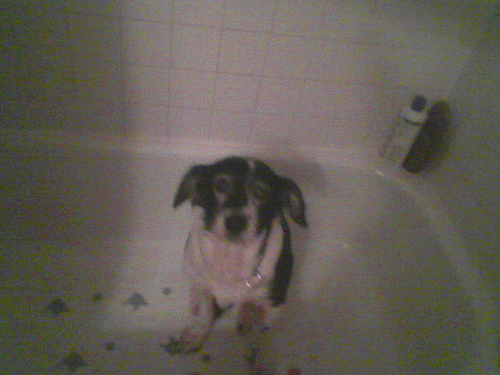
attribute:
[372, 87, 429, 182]
bottles — shampoo, soap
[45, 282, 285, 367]
pattern — GRIPPY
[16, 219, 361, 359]
floor — TUB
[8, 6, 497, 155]
wall — tiled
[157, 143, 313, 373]
dog — black, white,  get a bath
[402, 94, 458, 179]
bottle — black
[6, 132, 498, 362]
tub — white, bath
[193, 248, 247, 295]
fur — white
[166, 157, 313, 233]
ears — down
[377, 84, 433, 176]
bottle — blue, white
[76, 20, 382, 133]
tile — white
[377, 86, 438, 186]
bottle — shampoo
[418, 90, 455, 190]
bottle — conditioner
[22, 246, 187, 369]
floor — tub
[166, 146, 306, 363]
dog — black, white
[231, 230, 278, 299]
collar — dog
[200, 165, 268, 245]
face — canine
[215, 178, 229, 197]
eye — canine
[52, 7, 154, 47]
tile — plain, white, bathroom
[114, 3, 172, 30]
tile — bathroom, plain, white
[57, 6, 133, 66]
tile — white, bathroom, plain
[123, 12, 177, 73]
tile — plain, bathroom, white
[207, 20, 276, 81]
tile — white, bathroom, plain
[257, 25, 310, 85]
tile — plain, bathroom, white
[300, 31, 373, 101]
tile — white, bathroom, plain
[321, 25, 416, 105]
tile — plain, white, bathroom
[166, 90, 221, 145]
tile — bathroom, white, plain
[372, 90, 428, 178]
bottle — white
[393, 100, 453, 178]
bottle — black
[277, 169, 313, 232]
ear — floppy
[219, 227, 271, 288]
collar — gray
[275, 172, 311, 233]
ear — black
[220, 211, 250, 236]
nose — black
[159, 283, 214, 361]
leg — white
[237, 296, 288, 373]
leg — white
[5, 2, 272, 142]
tile — white